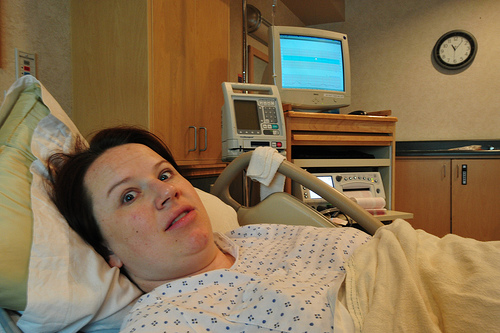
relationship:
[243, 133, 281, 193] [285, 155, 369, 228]
cloth on bar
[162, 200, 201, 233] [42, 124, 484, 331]
mouth of a person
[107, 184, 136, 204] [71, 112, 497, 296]
eye of person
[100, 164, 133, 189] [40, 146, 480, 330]
eyebrow of person